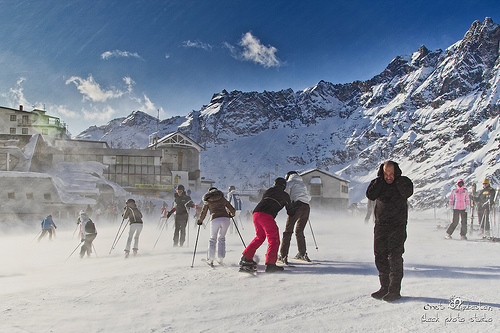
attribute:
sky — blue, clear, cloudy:
[2, 1, 498, 135]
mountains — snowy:
[74, 14, 500, 211]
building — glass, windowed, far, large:
[26, 131, 211, 222]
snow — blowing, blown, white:
[0, 208, 500, 332]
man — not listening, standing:
[365, 154, 416, 304]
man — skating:
[236, 176, 290, 273]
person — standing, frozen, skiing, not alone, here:
[445, 177, 478, 245]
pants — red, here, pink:
[238, 205, 284, 269]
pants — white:
[205, 216, 234, 260]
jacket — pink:
[445, 179, 474, 213]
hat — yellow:
[482, 179, 493, 186]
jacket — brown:
[197, 190, 237, 221]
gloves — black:
[376, 160, 405, 176]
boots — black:
[375, 277, 403, 304]